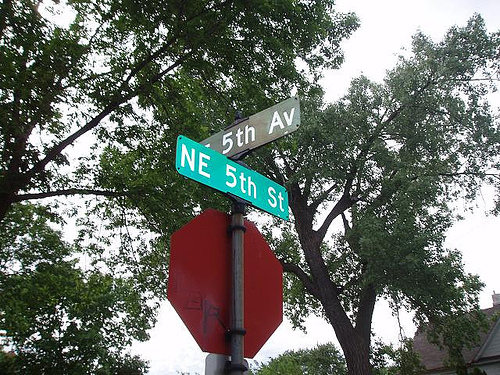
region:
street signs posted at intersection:
[158, 90, 314, 229]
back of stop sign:
[158, 200, 288, 362]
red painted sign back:
[162, 197, 288, 362]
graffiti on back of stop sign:
[186, 280, 237, 345]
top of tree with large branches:
[286, 16, 498, 367]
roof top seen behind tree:
[394, 284, 499, 374]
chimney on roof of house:
[488, 285, 498, 309]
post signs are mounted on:
[224, 175, 261, 373]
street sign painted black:
[203, 110, 302, 142]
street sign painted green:
[170, 144, 302, 214]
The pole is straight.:
[213, 128, 255, 373]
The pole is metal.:
[217, 127, 252, 372]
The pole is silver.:
[217, 111, 261, 373]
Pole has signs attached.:
[214, 105, 264, 373]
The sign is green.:
[176, 130, 301, 221]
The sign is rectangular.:
[169, 130, 319, 222]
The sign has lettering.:
[161, 128, 301, 231]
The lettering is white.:
[171, 132, 302, 224]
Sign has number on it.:
[168, 133, 300, 230]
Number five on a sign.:
[166, 126, 315, 239]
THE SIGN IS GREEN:
[166, 132, 304, 222]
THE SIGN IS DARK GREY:
[188, 91, 315, 166]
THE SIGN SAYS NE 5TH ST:
[177, 141, 289, 219]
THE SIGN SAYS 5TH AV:
[188, 109, 305, 151]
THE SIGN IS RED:
[153, 203, 294, 363]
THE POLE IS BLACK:
[216, 188, 260, 373]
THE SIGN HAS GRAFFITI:
[180, 281, 227, 347]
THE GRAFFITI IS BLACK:
[181, 282, 228, 349]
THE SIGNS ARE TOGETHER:
[161, 91, 302, 373]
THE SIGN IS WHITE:
[202, 351, 248, 373]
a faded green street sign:
[212, 94, 299, 156]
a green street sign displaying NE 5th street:
[177, 131, 289, 220]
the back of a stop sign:
[167, 208, 283, 357]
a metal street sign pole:
[230, 205, 246, 374]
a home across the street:
[411, 292, 498, 374]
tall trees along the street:
[0, 1, 169, 374]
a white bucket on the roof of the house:
[490, 288, 498, 306]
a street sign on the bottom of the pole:
[203, 351, 251, 374]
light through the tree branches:
[0, 1, 307, 94]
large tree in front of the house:
[301, 1, 498, 374]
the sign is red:
[153, 203, 288, 370]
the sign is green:
[171, 135, 303, 223]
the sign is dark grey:
[192, 89, 309, 169]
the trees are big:
[0, 0, 497, 373]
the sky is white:
[0, 0, 498, 373]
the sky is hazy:
[0, 0, 497, 373]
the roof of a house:
[396, 293, 498, 373]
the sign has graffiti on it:
[182, 287, 236, 351]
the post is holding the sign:
[223, 197, 253, 373]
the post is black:
[228, 204, 250, 374]